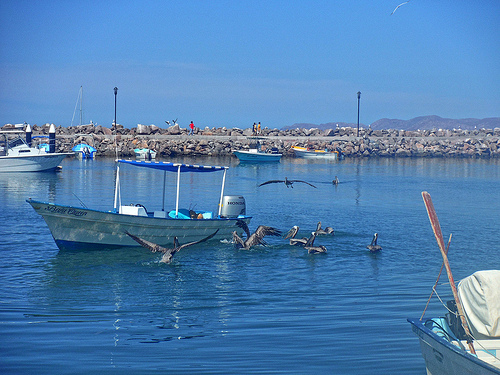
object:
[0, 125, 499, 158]
beach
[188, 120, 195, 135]
person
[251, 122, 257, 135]
person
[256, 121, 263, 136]
person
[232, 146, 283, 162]
boat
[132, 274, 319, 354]
ripples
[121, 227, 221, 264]
bird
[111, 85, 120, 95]
street lamp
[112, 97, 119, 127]
pole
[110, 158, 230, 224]
canopy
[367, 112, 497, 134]
mountain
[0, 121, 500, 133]
horizon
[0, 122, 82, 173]
boat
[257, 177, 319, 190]
pelican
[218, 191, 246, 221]
motor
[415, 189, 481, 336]
oar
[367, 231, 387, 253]
birds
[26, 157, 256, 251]
boat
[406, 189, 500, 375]
boat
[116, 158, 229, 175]
roof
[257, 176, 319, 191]
bird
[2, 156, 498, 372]
water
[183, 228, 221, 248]
wing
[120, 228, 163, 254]
wing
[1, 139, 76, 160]
dock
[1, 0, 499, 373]
air